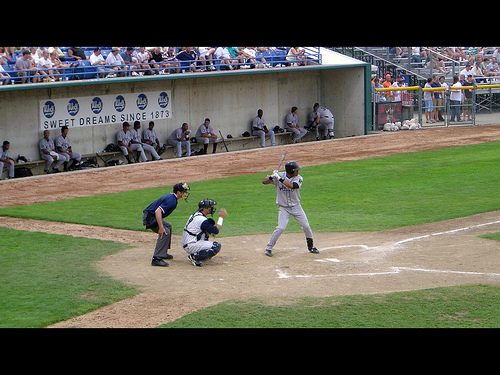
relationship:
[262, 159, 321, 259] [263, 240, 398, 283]
batter standing in batter's box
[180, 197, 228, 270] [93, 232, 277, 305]
catcher crouched in dirt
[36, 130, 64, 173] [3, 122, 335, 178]
player sitting on bench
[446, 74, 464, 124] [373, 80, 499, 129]
spectator behind fence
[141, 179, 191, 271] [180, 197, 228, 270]
umpire behind catcher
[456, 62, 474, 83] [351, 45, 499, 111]
spectator sitting in stands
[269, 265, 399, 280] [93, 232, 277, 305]
line painted in dirt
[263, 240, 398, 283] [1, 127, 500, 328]
batter's box at a field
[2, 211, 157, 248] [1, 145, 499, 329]
path inside of grass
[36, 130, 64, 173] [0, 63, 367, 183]
player inside of area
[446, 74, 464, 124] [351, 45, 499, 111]
spectator sitting in stands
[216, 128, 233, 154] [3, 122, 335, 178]
bat leaning on bench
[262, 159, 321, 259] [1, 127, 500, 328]
batter on a field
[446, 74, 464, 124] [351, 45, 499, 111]
spectator watching in stands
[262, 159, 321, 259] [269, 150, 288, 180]
batter holding bat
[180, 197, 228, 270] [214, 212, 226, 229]
catcher wearing band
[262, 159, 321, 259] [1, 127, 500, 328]
batter playing on field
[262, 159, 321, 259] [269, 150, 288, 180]
batter about to swing bat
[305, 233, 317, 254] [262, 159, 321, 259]
shin guard worn on batter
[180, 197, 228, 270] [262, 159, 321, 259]
catcher behind batter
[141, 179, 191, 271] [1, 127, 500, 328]
umpire on field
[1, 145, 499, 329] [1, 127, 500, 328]
grass growing on field